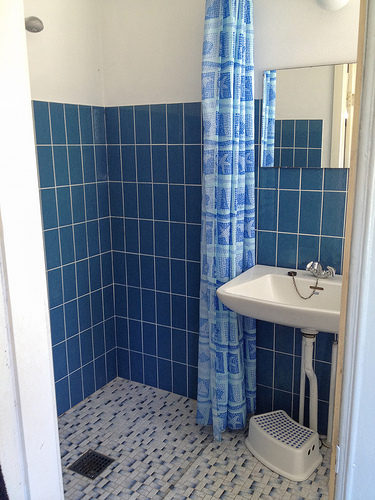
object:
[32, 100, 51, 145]
tiles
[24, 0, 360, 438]
walls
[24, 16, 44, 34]
shower head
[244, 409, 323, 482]
stool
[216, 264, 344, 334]
sink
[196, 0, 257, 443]
shower curtain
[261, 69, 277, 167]
reflection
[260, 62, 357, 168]
mirror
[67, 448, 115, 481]
drain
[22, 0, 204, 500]
shower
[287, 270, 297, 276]
sink plug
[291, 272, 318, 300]
chain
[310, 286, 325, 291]
overflow opening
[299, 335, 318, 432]
pipes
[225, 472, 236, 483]
tiles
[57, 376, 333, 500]
floor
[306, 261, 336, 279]
water fixtures